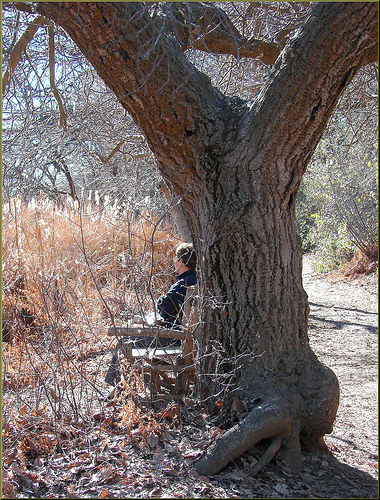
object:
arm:
[156, 282, 178, 320]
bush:
[294, 110, 380, 273]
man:
[103, 244, 198, 401]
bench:
[107, 285, 197, 396]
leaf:
[146, 431, 158, 448]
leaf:
[97, 487, 113, 497]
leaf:
[20, 403, 27, 414]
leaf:
[229, 466, 245, 482]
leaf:
[212, 399, 223, 414]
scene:
[2, 2, 378, 417]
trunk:
[138, 132, 344, 470]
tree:
[3, 0, 380, 475]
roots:
[193, 399, 302, 476]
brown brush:
[0, 191, 193, 497]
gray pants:
[104, 335, 180, 387]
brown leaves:
[3, 363, 276, 499]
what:
[18, 190, 105, 320]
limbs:
[247, 0, 380, 166]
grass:
[323, 249, 374, 289]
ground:
[321, 290, 364, 358]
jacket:
[157, 269, 197, 332]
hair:
[175, 243, 197, 268]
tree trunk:
[190, 221, 309, 350]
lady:
[103, 243, 197, 397]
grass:
[1, 184, 183, 498]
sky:
[27, 62, 50, 97]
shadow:
[308, 301, 380, 335]